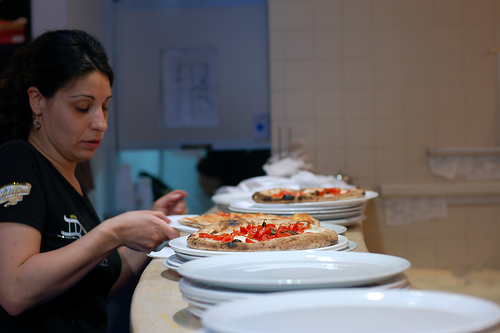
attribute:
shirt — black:
[12, 148, 121, 305]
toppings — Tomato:
[209, 221, 386, 269]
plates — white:
[212, 260, 387, 320]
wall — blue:
[125, 21, 277, 162]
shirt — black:
[0, 139, 121, 330]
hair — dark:
[5, 25, 116, 142]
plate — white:
[250, 197, 377, 207]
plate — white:
[163, 213, 348, 235]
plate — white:
[167, 234, 349, 257]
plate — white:
[177, 249, 412, 291]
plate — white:
[202, 287, 499, 332]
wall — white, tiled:
[270, 9, 497, 172]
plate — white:
[178, 246, 440, 296]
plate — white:
[159, 216, 349, 255]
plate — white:
[212, 188, 389, 218]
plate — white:
[187, 293, 497, 332]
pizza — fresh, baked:
[182, 217, 341, 255]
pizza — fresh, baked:
[247, 182, 367, 207]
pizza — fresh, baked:
[175, 210, 323, 235]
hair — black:
[37, 45, 80, 67]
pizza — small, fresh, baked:
[178, 208, 350, 258]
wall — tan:
[272, 0, 497, 270]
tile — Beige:
[311, 115, 348, 149]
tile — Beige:
[341, 84, 378, 119]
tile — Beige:
[340, 55, 377, 92]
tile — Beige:
[279, 23, 314, 63]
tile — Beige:
[340, 27, 375, 62]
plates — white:
[172, 243, 499, 328]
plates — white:
[153, 135, 415, 232]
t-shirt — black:
[4, 132, 122, 331]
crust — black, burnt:
[190, 228, 339, 252]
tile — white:
[281, 11, 483, 245]